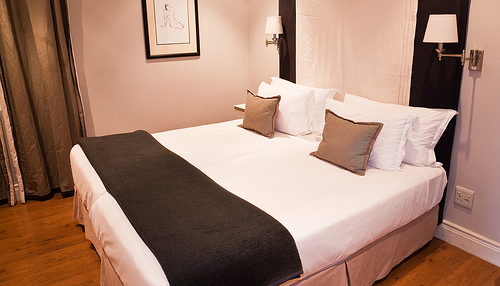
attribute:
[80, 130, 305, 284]
blanket — black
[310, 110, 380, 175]
pillow — small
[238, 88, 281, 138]
pillow — small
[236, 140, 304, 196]
sheet — white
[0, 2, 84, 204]
curtain — light brown